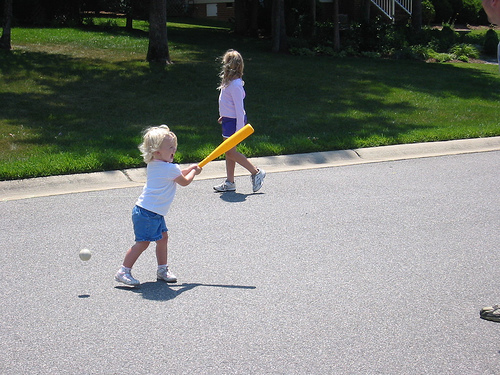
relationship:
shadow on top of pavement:
[77, 290, 101, 307] [3, 142, 492, 374]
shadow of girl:
[77, 290, 101, 307] [206, 50, 253, 202]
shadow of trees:
[77, 290, 101, 307] [234, 0, 310, 63]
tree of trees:
[136, 0, 182, 74] [234, 0, 310, 63]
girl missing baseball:
[206, 50, 253, 202] [75, 248, 93, 261]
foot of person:
[148, 257, 178, 278] [470, 298, 496, 322]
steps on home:
[381, 12, 411, 35] [183, 3, 243, 23]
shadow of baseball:
[77, 290, 101, 307] [75, 248, 93, 261]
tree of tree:
[136, 0, 182, 74] [1, 18, 17, 56]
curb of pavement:
[323, 137, 377, 164] [0, 140, 500, 374]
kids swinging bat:
[113, 121, 214, 289] [195, 117, 257, 172]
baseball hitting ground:
[75, 248, 93, 261] [327, 215, 394, 252]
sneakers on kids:
[103, 258, 172, 282] [113, 121, 214, 289]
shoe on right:
[211, 175, 238, 192] [402, 155, 464, 223]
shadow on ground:
[77, 290, 101, 307] [327, 215, 394, 252]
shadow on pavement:
[77, 290, 101, 307] [3, 142, 492, 374]